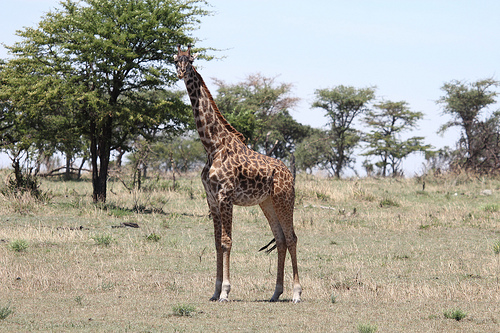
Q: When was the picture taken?
A: During the day.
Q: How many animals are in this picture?
A: One.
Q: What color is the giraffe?
A: Brown and white.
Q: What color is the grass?
A: Brown.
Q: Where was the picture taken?
A: Outside in field.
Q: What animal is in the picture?
A: Giraffe.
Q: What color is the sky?
A: Blue.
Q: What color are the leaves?
A: Green.